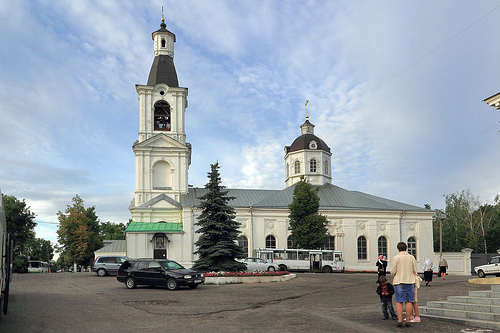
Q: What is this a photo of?
A: A church.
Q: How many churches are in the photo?
A: One.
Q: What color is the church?
A: White.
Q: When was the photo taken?
A: Daytime.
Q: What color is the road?
A: Black.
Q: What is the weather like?
A: Cloudy.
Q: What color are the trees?
A: Green.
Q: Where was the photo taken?
A: Beside a church.